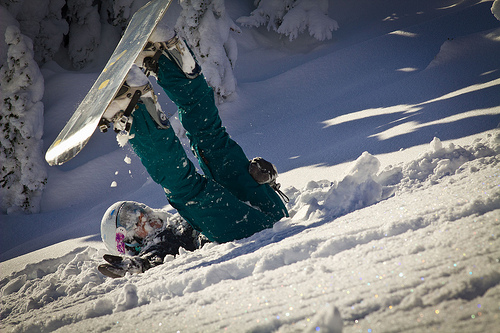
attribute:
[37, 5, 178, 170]
snowboard — black, yellow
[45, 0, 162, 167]
bottom — black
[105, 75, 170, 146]
ski boots — white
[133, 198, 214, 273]
coat — dark 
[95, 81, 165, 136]
boots — grey 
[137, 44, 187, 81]
boots — grey 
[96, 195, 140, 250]
helmet — white 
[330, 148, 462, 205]
field — covered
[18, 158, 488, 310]
field — covered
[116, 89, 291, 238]
suit — snow suit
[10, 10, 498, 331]
snow — white  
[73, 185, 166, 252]
helmet — white  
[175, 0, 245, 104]
branch — tree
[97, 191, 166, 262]
hat — white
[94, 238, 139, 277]
ski gloves — black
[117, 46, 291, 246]
snow pants — green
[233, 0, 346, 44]
tree branch — covered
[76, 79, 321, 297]
person — snowboarding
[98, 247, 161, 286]
black mitten — black 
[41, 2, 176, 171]
board — black  , yellow   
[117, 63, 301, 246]
pants — green 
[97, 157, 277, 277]
gloves — dark  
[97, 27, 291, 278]
person — wearing